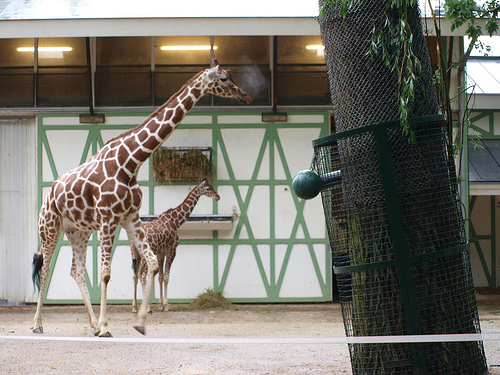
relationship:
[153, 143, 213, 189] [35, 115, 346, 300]
basket attached to wall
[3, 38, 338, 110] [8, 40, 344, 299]
windows are attached to wall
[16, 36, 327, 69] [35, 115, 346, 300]
lights inside wall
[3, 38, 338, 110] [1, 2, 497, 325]
windows are on outside of building